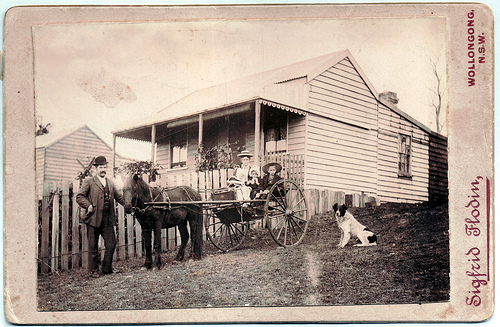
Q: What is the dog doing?
A: Sitting.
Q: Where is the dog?
A: Near the house.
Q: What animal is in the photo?
A: Dog.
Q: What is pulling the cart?
A: Horse.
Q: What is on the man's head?
A: Hat.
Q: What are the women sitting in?
A: Cart.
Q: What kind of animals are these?
A: Horse and cow.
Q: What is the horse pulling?
A: Carriage.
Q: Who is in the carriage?
A: Two people in hats.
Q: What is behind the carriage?
A: Wooden house.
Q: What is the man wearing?
A: Suit.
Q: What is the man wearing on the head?
A: Hat.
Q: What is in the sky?
A: Cloud.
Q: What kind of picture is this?
A: Sepia tone.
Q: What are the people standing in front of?
A: Wooden fence.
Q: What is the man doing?
A: Holding the horse.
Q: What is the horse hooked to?
A: A small carriage.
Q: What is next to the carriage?
A: A black and white dog.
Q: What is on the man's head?
A: A black hat.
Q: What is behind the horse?
A: A white fence.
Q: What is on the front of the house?
A: A front porch.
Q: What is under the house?
A: Shabby grass.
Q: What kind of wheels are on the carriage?
A: Wooden wheels.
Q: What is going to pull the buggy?
A: A horse.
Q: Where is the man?
A: Standing in front of the horse.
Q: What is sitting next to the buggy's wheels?
A: A dog.